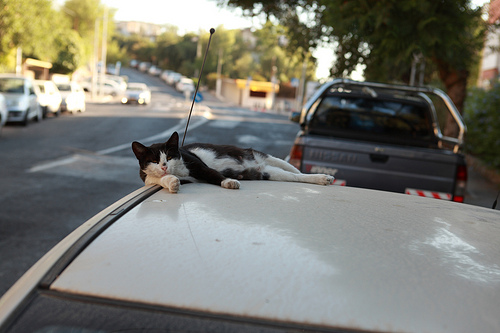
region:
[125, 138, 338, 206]
cat on car hood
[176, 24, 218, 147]
antenna on car roof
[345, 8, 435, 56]
green leaves of tree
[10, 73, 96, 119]
cars parked on street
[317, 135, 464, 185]
bed on back of truck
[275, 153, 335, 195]
white legs on cat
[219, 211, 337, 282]
white hoof of car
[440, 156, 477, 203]
brake light on truck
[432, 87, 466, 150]
metal bars on truck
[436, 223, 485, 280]
light reflection on roof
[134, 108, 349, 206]
a cat laying on a car roof.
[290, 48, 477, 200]
a parked truck on a street.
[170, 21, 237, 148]
a car radio antenna.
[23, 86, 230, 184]
a white line on a road.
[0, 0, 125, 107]
a bunch of trees on a road.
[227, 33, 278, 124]
a small building near trees.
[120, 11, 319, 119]
a forest of trees near a street.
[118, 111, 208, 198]
the head of a kitty cat.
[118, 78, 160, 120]
a parked car.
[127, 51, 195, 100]
a row of parked cars.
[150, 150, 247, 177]
cat on the vehicle.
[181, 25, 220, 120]
antenna on the vehicle.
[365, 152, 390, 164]
handle on back of truck.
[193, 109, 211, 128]
white line on road.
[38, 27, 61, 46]
leaves on the tree.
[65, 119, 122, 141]
blacktop on the road.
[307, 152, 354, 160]
word on the truck.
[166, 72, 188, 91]
cars parked along road.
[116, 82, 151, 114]
car in the street.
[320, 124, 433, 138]
bed of pickup truck.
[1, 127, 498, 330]
black and white cat lying on roof of white car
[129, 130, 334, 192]
black and white cat lounging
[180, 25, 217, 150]
car radio antenna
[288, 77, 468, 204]
small pickup truck with roll bars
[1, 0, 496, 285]
street lined with trees and parked cars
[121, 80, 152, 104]
car with headlights on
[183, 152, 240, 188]
black cat leg with white paw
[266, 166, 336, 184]
white back cat leg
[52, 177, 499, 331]
white car roof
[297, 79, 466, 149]
roll bars on pickup truck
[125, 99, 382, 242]
cat on top of the car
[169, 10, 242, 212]
antenna is next to the cat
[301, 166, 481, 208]
orange and white stripes on the back of vehicle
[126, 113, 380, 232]
cat is black and white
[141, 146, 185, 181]
black spot on the cat's face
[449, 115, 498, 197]
sidewalk is next to the vehicles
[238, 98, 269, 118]
caution cones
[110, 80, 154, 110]
headlights are on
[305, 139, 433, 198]
NISSAN on the back of truck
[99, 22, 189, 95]
road goes up a hill